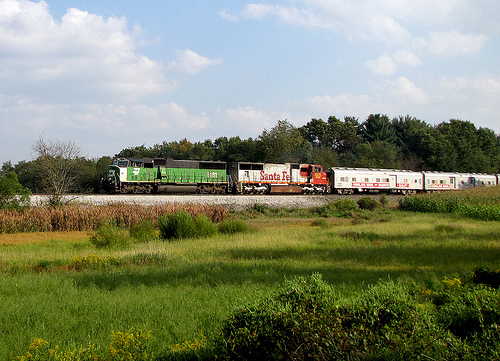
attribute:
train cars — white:
[329, 160, 497, 201]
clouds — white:
[246, 31, 338, 74]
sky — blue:
[21, 10, 492, 127]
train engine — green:
[87, 128, 234, 207]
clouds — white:
[8, 46, 122, 122]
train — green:
[101, 153, 498, 199]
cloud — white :
[3, 0, 168, 97]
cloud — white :
[216, 0, 493, 114]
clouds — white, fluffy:
[334, 68, 491, 115]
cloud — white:
[162, 42, 220, 79]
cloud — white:
[370, 71, 434, 109]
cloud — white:
[211, 98, 273, 129]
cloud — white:
[407, 28, 491, 60]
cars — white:
[164, 149, 405, 197]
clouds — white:
[228, 5, 498, 115]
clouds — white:
[1, 2, 223, 116]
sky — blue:
[0, 0, 499, 115]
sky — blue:
[26, 6, 498, 174]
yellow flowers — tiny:
[17, 320, 212, 359]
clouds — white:
[1, 0, 221, 147]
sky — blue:
[1, 0, 499, 166]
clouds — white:
[0, 0, 498, 110]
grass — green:
[2, 207, 494, 359]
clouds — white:
[0, 0, 497, 168]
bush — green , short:
[206, 273, 499, 359]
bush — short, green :
[219, 269, 369, 356]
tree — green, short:
[389, 110, 461, 172]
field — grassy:
[5, 206, 497, 360]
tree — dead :
[31, 132, 93, 213]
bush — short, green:
[156, 270, 498, 359]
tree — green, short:
[326, 111, 406, 178]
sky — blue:
[282, 56, 357, 90]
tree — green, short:
[436, 116, 498, 174]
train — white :
[235, 161, 306, 193]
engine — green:
[107, 158, 230, 188]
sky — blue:
[3, 3, 499, 147]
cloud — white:
[29, 22, 163, 114]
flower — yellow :
[37, 319, 169, 359]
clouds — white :
[290, 79, 437, 117]